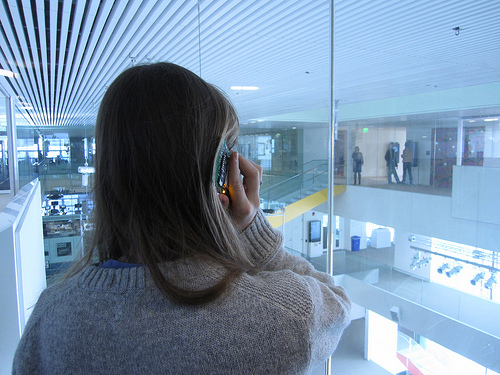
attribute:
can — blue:
[345, 234, 370, 253]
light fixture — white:
[406, 253, 433, 271]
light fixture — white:
[433, 257, 461, 279]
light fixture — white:
[469, 267, 489, 297]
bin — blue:
[348, 231, 363, 250]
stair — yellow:
[310, 182, 325, 192]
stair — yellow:
[301, 187, 318, 195]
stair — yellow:
[290, 191, 309, 201]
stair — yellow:
[283, 193, 298, 205]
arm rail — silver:
[276, 172, 331, 200]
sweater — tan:
[15, 260, 353, 372]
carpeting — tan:
[412, 284, 497, 319]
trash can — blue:
[349, 236, 365, 259]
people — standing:
[351, 140, 413, 185]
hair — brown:
[57, 62, 278, 308]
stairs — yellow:
[262, 165, 350, 236]